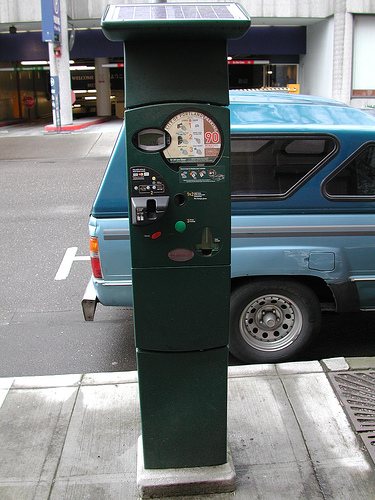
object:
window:
[258, 62, 300, 90]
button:
[172, 218, 186, 233]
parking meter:
[98, 0, 252, 470]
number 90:
[203, 128, 220, 147]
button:
[146, 227, 164, 243]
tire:
[224, 282, 312, 362]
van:
[77, 101, 349, 334]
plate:
[330, 351, 362, 473]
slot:
[198, 223, 212, 250]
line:
[51, 239, 85, 284]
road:
[8, 154, 137, 366]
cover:
[306, 247, 338, 273]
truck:
[83, 218, 345, 344]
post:
[96, 4, 252, 464]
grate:
[325, 367, 374, 470]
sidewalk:
[1, 355, 372, 498]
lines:
[52, 246, 88, 280]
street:
[1, 134, 373, 374]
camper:
[92, 93, 374, 216]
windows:
[229, 135, 374, 196]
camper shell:
[92, 93, 374, 217]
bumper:
[81, 275, 96, 324]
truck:
[79, 91, 374, 366]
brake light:
[88, 233, 102, 279]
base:
[135, 431, 235, 498]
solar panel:
[102, 2, 247, 23]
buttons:
[149, 220, 187, 239]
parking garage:
[0, 0, 371, 133]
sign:
[40, 1, 60, 41]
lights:
[88, 235, 102, 279]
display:
[133, 128, 171, 153]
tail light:
[88, 235, 102, 280]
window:
[231, 136, 337, 195]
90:
[205, 130, 218, 144]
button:
[174, 220, 184, 232]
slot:
[137, 206, 162, 212]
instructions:
[161, 110, 221, 170]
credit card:
[131, 195, 167, 227]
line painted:
[59, 242, 79, 285]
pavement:
[36, 307, 66, 338]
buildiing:
[11, 8, 363, 101]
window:
[28, 65, 62, 126]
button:
[150, 212, 193, 246]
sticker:
[163, 109, 222, 159]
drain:
[326, 357, 361, 441]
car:
[53, 86, 363, 355]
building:
[311, 10, 362, 76]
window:
[339, 23, 363, 84]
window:
[363, 16, 364, 95]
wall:
[305, 30, 339, 94]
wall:
[334, 16, 341, 101]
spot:
[45, 248, 73, 287]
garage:
[5, 18, 334, 109]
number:
[204, 119, 228, 155]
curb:
[20, 362, 93, 382]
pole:
[39, 29, 72, 125]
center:
[44, 8, 65, 126]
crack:
[273, 362, 332, 494]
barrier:
[224, 80, 305, 94]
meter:
[98, 0, 243, 487]